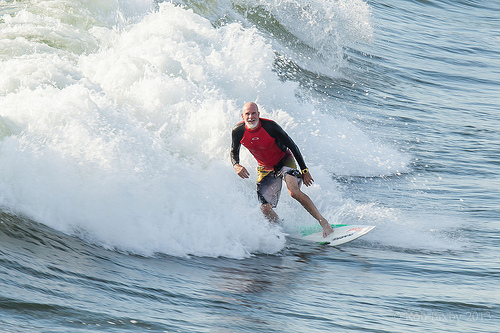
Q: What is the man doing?
A: Surfing.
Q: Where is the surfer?
A: In the ocean.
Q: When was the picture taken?
A: During daytime.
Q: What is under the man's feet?
A: Surfboard.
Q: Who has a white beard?
A: Man surfing.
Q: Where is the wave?
A: In ocean.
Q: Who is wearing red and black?
A: The surfer.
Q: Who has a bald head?
A: The man.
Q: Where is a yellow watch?
A: Around man's wrist.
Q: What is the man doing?
A: The man is surfing.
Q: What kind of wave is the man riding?
A: The man is riding a foamy wave.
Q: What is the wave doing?
A: The wave is peaking and crashing.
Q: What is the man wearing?
A: The man is wearing a wet suit and shorts.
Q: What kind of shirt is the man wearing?
A: The man is wearing a wet suit shirt.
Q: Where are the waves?
A: In the ocean.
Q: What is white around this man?
A: Spray from the wave.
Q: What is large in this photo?
A: Wave crashing.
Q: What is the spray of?
A: Water.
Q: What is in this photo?
A: A man surfing a wave.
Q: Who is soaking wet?
A: An old man.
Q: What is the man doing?
A: Surfing.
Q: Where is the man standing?
A: On the board.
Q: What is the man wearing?
A: A red and black shirt.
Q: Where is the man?
A: In front of the wave.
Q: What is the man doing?
A: Surfing.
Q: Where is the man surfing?
A: Ocean.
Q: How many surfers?
A: One.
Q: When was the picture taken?
A: Daytime.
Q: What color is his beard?
A: White.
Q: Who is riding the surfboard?
A: Surfer.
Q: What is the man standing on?
A: Surfboard.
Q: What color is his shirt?
A: Red and black.